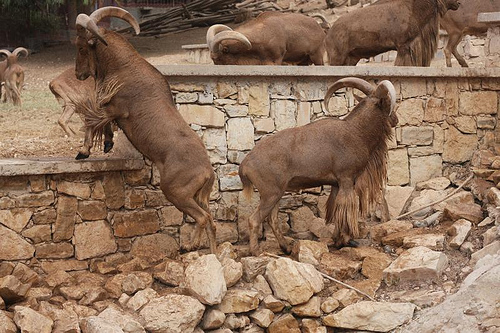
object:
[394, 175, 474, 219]
wood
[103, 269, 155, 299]
stones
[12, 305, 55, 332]
rock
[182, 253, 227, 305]
large rock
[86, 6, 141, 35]
horns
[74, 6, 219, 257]
ram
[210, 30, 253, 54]
horn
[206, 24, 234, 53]
horn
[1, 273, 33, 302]
rocks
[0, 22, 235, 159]
ground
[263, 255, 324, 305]
stone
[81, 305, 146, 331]
stone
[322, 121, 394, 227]
hair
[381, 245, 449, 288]
large rock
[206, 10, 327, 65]
ram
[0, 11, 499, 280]
wall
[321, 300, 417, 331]
rock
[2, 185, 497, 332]
ground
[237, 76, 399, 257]
ram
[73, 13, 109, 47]
horns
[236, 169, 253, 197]
brown tail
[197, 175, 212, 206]
brown tail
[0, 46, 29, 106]
ram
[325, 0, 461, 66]
ram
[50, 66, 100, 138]
ram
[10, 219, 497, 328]
stone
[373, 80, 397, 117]
horn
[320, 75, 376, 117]
horn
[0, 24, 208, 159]
dirt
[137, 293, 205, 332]
rock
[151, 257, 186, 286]
rock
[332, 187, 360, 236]
hair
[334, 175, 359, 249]
leg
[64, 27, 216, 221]
fur